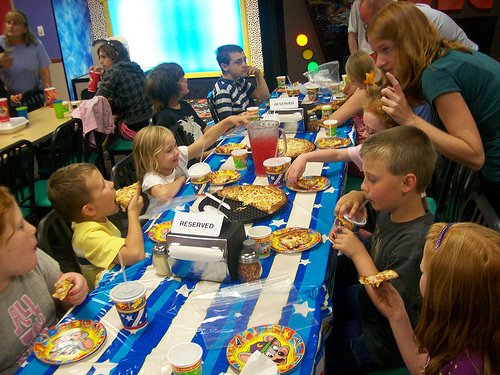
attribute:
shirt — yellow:
[68, 221, 127, 286]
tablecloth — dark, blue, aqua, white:
[17, 82, 366, 372]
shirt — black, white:
[208, 73, 256, 119]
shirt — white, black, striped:
[210, 76, 255, 122]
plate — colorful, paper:
[222, 321, 306, 372]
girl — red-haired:
[353, 216, 483, 373]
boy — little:
[42, 158, 153, 288]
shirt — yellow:
[63, 215, 129, 291]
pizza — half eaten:
[211, 182, 291, 214]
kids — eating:
[15, 120, 420, 338]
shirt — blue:
[365, 221, 436, 277]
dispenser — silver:
[173, 229, 236, 259]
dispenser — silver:
[185, 249, 245, 267]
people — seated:
[150, 44, 427, 341]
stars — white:
[91, 215, 204, 335]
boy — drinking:
[265, 148, 406, 268]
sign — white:
[150, 183, 266, 343]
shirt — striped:
[199, 70, 254, 114]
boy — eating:
[72, 150, 126, 222]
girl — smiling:
[124, 153, 204, 184]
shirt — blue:
[389, 60, 482, 101]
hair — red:
[369, 21, 425, 37]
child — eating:
[37, 170, 199, 292]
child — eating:
[377, 224, 497, 314]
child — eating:
[11, 160, 185, 264]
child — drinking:
[280, 62, 481, 247]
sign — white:
[162, 201, 244, 248]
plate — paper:
[281, 218, 335, 275]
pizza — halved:
[212, 152, 272, 222]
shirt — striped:
[221, 68, 269, 142]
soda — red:
[235, 144, 277, 161]